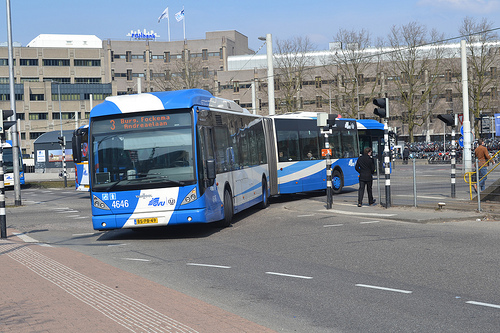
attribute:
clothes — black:
[356, 157, 386, 209]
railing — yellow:
[444, 163, 494, 190]